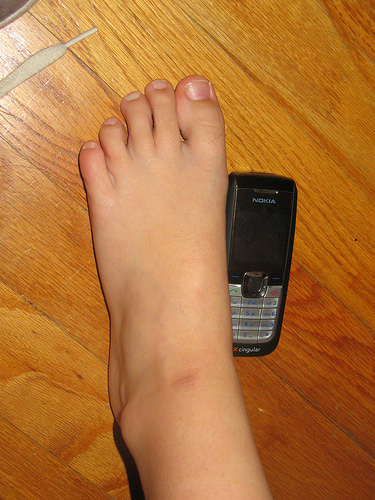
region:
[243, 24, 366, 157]
part of the wooden floor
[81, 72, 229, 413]
the child's little foot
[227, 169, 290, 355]
the nokia cell phone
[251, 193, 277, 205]
the nokia logo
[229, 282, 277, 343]
the cell phone key pad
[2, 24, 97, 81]
the white shoe lace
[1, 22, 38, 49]
the reflection on the floor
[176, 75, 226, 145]
the child's big toe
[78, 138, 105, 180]
the child's pinky toe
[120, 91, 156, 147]
the child's middle toe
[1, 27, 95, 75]
end of a white shoelace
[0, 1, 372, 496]
brown wooden floor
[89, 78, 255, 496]
person's foot is bare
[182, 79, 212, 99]
toenail on the big toe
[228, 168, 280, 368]
old black Nokia cell phone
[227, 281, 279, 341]
silver button pad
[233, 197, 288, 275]
black phone screen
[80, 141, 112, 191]
pinky toe and toenail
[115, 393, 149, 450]
ankle bone on foot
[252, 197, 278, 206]
white logo on cell phone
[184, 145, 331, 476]
A cellphone is visible.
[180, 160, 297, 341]
A cellphone is visible.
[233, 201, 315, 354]
A cellphone is visible.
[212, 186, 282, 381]
A cellphone is visible.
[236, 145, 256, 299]
A cellphone is visible.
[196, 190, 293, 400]
the old school cell phone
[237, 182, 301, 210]
the word nokia on the phone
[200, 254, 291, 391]
the silver numbers on the phone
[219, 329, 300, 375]
the word cingular on the phone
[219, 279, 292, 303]
the green phone symbol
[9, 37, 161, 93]
the white shoe lace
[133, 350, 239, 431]
the scar on the ankle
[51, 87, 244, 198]
the toes on the foot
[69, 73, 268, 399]
the entire foot in view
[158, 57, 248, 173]
the biggest of toes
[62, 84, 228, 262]
foot next to phone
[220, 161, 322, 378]
phone with blue numbers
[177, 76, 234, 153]
big toe of foot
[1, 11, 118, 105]
shoelace in the photo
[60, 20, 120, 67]
white tip of the shoelace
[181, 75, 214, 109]
toenail on foot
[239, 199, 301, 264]
screen of the phone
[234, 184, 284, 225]
label of the phone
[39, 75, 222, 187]
five toes on foot